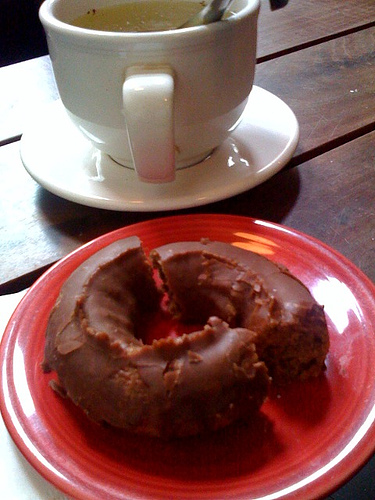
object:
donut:
[40, 235, 330, 440]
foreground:
[16, 67, 360, 493]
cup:
[37, 0, 261, 185]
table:
[0, 0, 375, 499]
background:
[0, 0, 50, 69]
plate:
[19, 82, 301, 214]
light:
[221, 119, 261, 158]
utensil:
[181, 0, 236, 29]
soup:
[53, 0, 238, 35]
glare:
[16, 209, 42, 234]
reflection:
[233, 136, 292, 187]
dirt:
[349, 88, 359, 93]